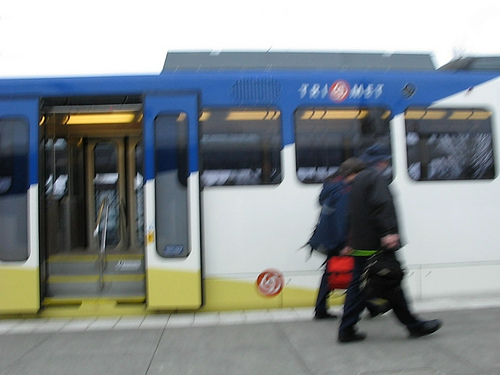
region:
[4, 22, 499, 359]
people walking in front of a train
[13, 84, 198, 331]
an open door on a train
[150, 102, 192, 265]
a window on a door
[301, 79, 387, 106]
foreign writing on a train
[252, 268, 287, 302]
a red logo on a train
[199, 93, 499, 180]
windows on a train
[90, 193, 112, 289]
a metal rail on a train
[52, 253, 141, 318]
steps on a train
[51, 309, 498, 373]
a sidewalk near a train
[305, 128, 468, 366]
people next to a train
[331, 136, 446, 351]
PERSON WALKING ON PLATFORM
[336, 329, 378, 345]
FOOT OF WALKING PERSON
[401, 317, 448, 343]
FOOT OF WALKING PERSON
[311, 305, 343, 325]
FOOT OF WALKING PERSON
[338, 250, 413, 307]
BACKPACK OF WALKING PERSON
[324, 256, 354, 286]
RED BAG OF WALKING PERSON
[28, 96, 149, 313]
OPEN DOOR AREA OF TRAIN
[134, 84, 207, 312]
DOOR OF BLUE AND YELLOW TRAIN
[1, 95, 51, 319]
DOOR OF BLUE AND YELLOW TRAIN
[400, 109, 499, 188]
PASSENGER WINDOW OF TRAIN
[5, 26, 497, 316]
a commuter train station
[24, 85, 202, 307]
an open door to a train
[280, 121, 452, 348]
two people walking briskly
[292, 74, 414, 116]
the logo for tri met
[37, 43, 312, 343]
a blue, white and yellow train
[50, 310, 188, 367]
a white and grey boarding platform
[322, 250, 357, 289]
a red messenger bag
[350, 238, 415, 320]
a black back pack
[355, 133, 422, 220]
a man wearing a blue hat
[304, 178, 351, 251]
a woman wearing a blue adirondack jacket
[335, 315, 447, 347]
Man wearing shoes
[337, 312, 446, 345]
Man is wearing shoes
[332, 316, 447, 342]
Man wearing black shoes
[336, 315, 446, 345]
Man is wearing black shoes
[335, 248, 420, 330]
Man wearing pants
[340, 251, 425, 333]
Man is wearing pants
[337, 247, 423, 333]
Man wearing dark blue pants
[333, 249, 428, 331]
Man is wearing dark blue pants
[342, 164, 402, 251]
Man wearing a jacket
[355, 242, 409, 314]
Man is holding a black bag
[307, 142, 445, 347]
two people walking near train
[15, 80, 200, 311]
entry to Trimet rapid transit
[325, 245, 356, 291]
red suitcase carried by commuter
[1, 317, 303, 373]
sidewalk near rapid transit entryway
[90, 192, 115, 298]
entryway handrail for steps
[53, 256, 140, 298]
Trimet entryway with stairway painted yellow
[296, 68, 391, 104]
trimet rapid transit company logo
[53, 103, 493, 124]
warm colored overhead lighting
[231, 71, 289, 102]
airflow ventilation grille on blue painted background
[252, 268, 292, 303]
red transit company logo